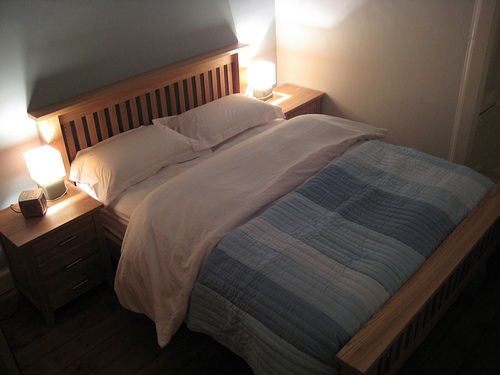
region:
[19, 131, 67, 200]
Lamp on the night stand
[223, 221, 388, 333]
blue blanket on the bed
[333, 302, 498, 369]
Foot board at the end of the bed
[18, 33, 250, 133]
Head board at the front of the bed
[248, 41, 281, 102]
lamp on a night stand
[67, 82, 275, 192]
Two pillows on a bed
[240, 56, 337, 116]
Night stand on the side of the bed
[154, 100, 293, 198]
Pillows on the bed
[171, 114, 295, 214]
white blanket on the bed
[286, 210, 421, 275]
blue blanket on the bed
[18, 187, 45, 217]
square alarm clock on the night stand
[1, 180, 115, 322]
small wooden brown night stand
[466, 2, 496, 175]
part of a closed white door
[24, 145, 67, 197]
square light on the night stand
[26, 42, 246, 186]
wooden head board with slats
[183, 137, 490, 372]
blue comforter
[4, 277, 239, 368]
part of wood floor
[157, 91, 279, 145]
white pillow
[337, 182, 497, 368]
wooden foot board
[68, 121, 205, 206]
white pillow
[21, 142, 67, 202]
lamp on the end table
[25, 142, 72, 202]
lamp is turned on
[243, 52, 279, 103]
lamp on other end table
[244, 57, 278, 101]
lamp is turned on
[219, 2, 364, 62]
light shining on wall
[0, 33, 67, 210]
light shining on wall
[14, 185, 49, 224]
radio clock on end table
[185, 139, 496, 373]
the comforter is blue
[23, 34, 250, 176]
the headboard is brown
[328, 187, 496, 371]
end of bed made of wood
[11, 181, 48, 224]
clock on a nightstand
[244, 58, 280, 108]
small lamp on a night stand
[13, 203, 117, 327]
Night stand next to the bed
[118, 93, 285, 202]
Pillow on top of a bed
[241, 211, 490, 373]
Blue blanket on the bed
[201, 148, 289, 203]
white blanket on the bed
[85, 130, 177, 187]
white pillow on the bed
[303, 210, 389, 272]
blue blanket on the bed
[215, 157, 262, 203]
white blanket on the bed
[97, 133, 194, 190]
pilow on the bed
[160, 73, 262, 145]
pillow on the bed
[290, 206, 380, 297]
sheet on the bed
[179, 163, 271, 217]
sheet on the bed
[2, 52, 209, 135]
headboard of the bed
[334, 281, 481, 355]
end of the bed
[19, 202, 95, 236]
desk near the bed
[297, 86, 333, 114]
desk near the bed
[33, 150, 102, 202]
light on the desk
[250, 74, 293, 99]
light on the desk